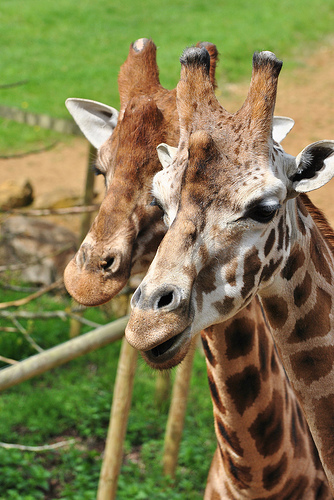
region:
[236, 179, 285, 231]
Giraffe's left eyeball.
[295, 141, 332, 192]
Giraffe's left ear.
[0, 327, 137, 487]
Wooden pole structure.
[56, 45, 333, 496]
Two giraffes side by side.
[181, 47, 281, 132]
Set of giraffe horns.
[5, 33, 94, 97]
Patch of bright green grass.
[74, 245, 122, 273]
Giraffe nostril openings.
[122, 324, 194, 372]
Giraffe's open mouth.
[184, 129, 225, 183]
Horn in middle of giraffe head.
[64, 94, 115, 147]
Right ear of giraffe.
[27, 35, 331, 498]
two giraffes standing next to each other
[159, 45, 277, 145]
the giraffe has horns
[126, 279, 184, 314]
the giraffe has a nose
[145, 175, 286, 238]
the giraffe has eyes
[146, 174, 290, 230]
the giraffe's eyes are black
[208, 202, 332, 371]
the giraffe has spots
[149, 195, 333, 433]
the giraffe is tan and brown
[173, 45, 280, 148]
the giraffe's horns are brown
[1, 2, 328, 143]
the grass is green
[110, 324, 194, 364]
the giraffe's mouth is open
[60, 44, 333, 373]
Two heads of giraffes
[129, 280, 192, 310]
Two nostrils of giraffe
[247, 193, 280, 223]
One eye of giraffe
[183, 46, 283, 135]
Two short giraffe horns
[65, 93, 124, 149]
White ear of giraffe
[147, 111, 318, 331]
Brown and white giraffe head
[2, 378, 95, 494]
Green vegetation on ground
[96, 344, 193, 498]
Two brown tree trunks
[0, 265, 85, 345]
Several fallen tree branches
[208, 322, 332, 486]
Two long giraffe necks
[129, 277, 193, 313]
Two nostrils of a giraffe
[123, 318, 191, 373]
Open mouth of giraffe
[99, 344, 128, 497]
Brown trunk of tree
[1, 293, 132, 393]
Tree trunk bending sideways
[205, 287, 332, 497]
Brown spots on giraffes' necks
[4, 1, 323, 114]
Green grass in background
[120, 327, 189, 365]
the giraffe has a mouth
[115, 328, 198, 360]
the mouth of the giraffe is open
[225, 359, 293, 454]
the giraffe has spots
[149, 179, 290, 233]
the eyes are black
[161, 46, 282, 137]
the horns are brown and black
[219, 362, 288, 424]
the spots are dark brown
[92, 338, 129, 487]
the post is wooden